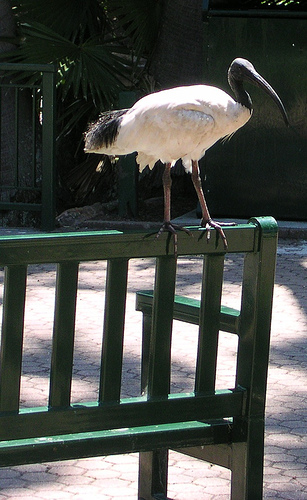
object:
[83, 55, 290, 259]
bird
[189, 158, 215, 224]
leg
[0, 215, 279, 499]
bench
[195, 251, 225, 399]
plank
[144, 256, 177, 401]
plank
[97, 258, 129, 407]
plank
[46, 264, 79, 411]
plank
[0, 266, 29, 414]
plank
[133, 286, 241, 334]
plank